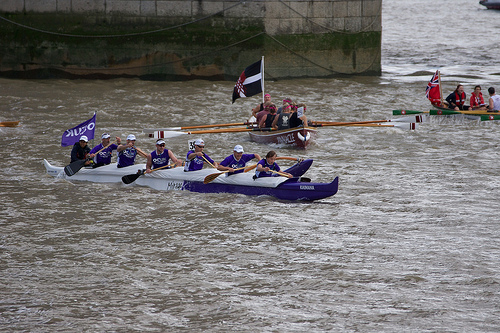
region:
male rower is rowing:
[183, 136, 215, 171]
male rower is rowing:
[146, 137, 176, 168]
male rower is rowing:
[95, 132, 115, 167]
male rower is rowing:
[118, 130, 144, 169]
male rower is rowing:
[222, 144, 257, 176]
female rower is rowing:
[253, 153, 290, 179]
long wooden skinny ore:
[202, 162, 258, 185]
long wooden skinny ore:
[151, 123, 256, 139]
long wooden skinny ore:
[313, 116, 424, 128]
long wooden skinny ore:
[308, 119, 414, 133]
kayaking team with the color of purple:
[36, 119, 333, 231]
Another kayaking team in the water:
[225, 48, 315, 148]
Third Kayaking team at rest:
[422, 57, 494, 137]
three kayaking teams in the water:
[17, 61, 496, 193]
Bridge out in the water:
[0, 1, 387, 76]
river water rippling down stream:
[0, 193, 366, 330]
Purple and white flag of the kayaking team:
[50, 105, 107, 152]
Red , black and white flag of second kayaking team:
[221, 43, 273, 112]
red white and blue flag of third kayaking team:
[421, 60, 455, 122]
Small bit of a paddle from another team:
[2, 116, 37, 152]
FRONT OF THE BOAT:
[186, 125, 338, 222]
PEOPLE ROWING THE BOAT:
[58, 117, 355, 221]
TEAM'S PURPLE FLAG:
[42, 97, 112, 185]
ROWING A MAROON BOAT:
[227, 56, 330, 156]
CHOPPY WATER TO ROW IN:
[37, 185, 467, 320]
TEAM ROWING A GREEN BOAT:
[390, 43, 496, 138]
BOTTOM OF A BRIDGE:
[15, 2, 408, 102]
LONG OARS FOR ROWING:
[137, 95, 427, 145]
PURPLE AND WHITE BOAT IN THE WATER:
[40, 106, 380, 227]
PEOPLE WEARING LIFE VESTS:
[410, 72, 498, 127]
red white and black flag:
[222, 49, 277, 99]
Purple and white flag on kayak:
[62, 116, 97, 142]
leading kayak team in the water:
[66, 116, 343, 198]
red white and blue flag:
[425, 63, 444, 110]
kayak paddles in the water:
[328, 102, 435, 147]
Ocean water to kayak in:
[46, 178, 241, 303]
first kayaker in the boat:
[261, 150, 295, 195]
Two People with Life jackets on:
[449, 82, 490, 114]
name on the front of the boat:
[296, 179, 319, 195]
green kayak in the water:
[384, 101, 498, 118]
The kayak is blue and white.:
[43, 147, 347, 202]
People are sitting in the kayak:
[48, 114, 345, 216]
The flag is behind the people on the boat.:
[238, 64, 318, 146]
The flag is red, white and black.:
[236, 51, 283, 107]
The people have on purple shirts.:
[192, 136, 282, 184]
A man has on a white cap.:
[228, 135, 248, 157]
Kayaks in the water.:
[36, 103, 481, 183]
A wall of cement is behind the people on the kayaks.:
[69, 17, 374, 73]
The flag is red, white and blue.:
[413, 62, 445, 124]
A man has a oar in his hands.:
[118, 167, 155, 187]